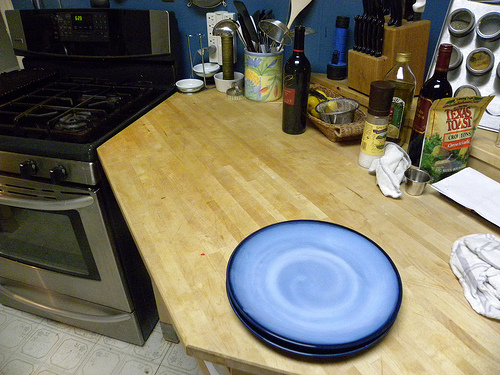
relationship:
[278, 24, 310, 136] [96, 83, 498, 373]
wine on counter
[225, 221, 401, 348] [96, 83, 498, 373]
plate on counter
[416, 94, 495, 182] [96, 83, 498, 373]
crouton bag on counter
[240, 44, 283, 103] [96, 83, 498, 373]
utensil holder on counter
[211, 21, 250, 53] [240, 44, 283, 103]
soup spoon in utensil holder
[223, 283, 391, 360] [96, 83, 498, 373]
plate on counter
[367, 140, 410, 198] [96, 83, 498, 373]
towel on counter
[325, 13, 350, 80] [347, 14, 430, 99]
flashlight next to knife block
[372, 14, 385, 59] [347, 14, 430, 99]
knife in knife block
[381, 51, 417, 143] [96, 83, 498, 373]
olive oil on counter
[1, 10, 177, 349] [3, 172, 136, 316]
stove has door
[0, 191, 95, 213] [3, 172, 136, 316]
handle on door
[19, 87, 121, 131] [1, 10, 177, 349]
burner on stove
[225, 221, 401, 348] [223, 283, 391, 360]
plate on plate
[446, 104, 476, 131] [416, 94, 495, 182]
lettering on crouton bag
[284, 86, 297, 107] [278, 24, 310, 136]
label on wine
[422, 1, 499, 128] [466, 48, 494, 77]
spice rack has cannister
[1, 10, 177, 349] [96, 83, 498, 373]
stove next to counter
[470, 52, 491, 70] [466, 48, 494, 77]
herbs in cannister